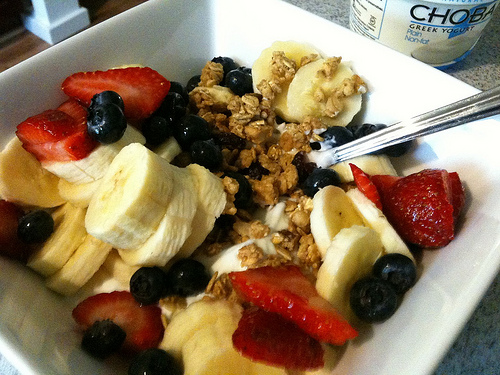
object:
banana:
[311, 223, 380, 313]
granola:
[247, 175, 280, 208]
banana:
[308, 185, 368, 263]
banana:
[0, 132, 61, 210]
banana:
[82, 142, 172, 246]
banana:
[27, 205, 86, 274]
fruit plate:
[0, 38, 475, 375]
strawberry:
[71, 292, 160, 348]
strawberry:
[229, 264, 355, 346]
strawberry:
[226, 300, 327, 374]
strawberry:
[61, 64, 169, 117]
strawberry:
[389, 167, 451, 246]